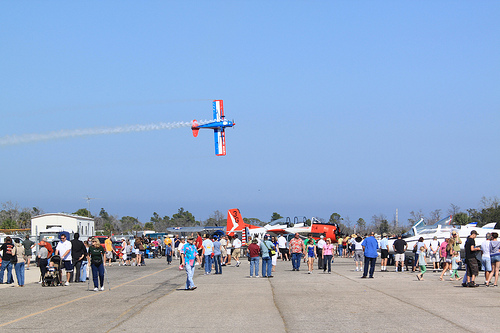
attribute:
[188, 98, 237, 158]
plane — red, white, blue, orange, flying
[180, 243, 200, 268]
shirt — white, blue, pink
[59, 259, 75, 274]
shorts — blue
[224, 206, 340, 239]
plane — red, white, orange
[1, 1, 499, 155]
sky — clear, blue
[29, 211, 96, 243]
hangar — white, manufactured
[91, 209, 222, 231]
trees — green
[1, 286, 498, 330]
ground — paved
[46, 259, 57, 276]
child — small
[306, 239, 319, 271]
woman — young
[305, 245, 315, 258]
shirt — sleeveless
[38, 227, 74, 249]
bus — white